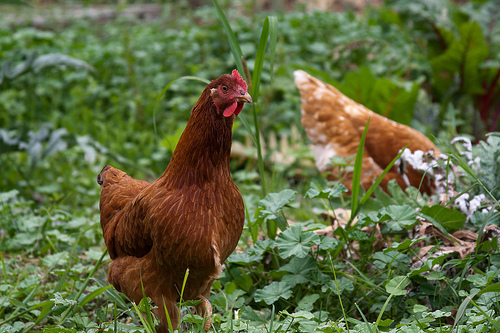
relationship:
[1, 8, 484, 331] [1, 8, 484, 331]
grass are in grass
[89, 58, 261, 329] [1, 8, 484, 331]
hen in grass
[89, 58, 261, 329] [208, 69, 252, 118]
hen has head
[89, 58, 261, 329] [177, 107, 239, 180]
hen has neck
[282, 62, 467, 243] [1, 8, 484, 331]
hen in grass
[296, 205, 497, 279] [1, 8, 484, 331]
dead leaves are in grass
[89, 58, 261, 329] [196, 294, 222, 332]
hen has claw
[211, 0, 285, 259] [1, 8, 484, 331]
tall weed in grass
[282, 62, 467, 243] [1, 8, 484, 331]
hen bent over in grass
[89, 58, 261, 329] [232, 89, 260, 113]
hen has beak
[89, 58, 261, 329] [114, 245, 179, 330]
hen has leg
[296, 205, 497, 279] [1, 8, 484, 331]
dead leaves in grass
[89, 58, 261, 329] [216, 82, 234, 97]
hen has eye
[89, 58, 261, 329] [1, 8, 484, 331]
hen walking in grass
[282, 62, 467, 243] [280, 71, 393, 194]
hen has wing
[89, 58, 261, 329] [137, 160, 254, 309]
hen has breast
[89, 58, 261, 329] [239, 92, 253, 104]
hen has beak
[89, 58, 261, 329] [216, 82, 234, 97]
hen has red eye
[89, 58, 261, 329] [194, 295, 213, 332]
hen has claw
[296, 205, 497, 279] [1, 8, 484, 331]
dead leaves are on grass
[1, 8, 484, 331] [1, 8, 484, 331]
grass in grass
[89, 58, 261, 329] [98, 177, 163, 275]
hen has wing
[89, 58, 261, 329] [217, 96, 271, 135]
hen has red skin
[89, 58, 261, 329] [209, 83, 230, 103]
hen has red cheek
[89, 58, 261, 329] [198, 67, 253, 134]
hen has head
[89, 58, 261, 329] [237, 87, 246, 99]
hen has holes in beak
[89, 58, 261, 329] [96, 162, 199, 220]
hen has back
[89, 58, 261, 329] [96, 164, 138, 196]
hen has back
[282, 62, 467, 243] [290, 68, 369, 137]
hen has back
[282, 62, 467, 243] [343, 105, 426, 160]
hen has back